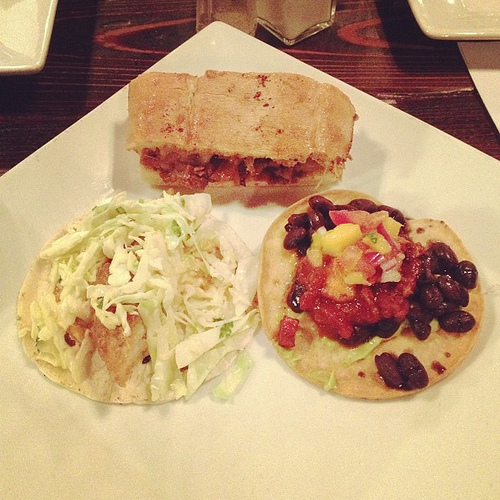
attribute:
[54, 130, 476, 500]
plate — white, sqaure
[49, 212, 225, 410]
tortilla — green, round, small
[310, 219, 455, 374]
beans — red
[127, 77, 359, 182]
bread — stuffed, round, sandwhich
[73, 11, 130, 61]
table — brown, wood, wooden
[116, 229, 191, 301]
lettuce — green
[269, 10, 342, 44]
salt shaker — brown